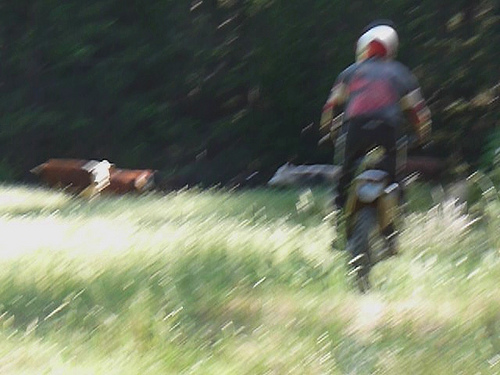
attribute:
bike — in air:
[327, 117, 424, 294]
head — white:
[77, 157, 112, 191]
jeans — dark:
[337, 96, 399, 219]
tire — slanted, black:
[345, 205, 384, 292]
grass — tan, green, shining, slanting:
[4, 207, 498, 374]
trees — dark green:
[0, 2, 498, 177]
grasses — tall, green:
[104, 204, 372, 324]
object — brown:
[32, 159, 153, 199]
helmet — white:
[346, 18, 414, 60]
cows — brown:
[21, 154, 192, 207]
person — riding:
[320, 16, 430, 246]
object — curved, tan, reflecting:
[73, 154, 115, 200]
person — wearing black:
[334, 25, 420, 212]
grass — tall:
[1, 182, 498, 374]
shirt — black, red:
[322, 67, 444, 151]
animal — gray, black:
[256, 151, 390, 242]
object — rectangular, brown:
[28, 132, 159, 207]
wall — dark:
[30, 46, 264, 141]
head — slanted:
[265, 155, 310, 185]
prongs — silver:
[363, 240, 394, 285]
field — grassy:
[59, 197, 394, 316]